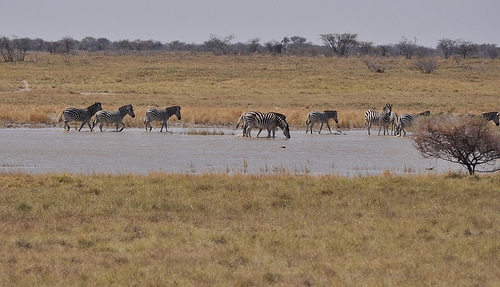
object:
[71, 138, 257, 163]
water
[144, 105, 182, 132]
zebras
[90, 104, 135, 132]
zebras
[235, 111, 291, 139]
zebra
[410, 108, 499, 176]
bush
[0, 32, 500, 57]
horizon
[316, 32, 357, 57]
trees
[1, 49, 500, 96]
grass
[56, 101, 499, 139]
herd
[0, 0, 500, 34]
sky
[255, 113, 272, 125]
stripes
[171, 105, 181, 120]
head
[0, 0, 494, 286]
african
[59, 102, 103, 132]
eight zebras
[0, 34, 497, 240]
shot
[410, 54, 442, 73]
bushes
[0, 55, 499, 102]
plain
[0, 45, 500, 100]
field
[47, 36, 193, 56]
distance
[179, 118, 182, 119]
nose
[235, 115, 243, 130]
tail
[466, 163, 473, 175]
trunk